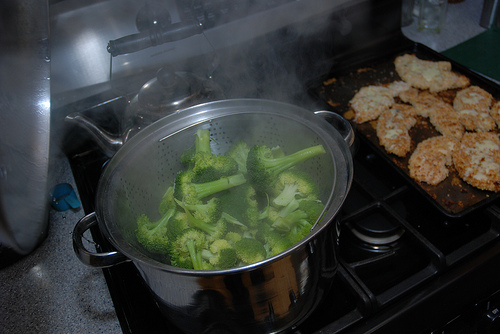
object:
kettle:
[63, 19, 227, 159]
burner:
[347, 205, 405, 254]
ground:
[320, 45, 352, 60]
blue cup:
[48, 182, 81, 212]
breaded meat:
[348, 53, 500, 191]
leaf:
[246, 144, 279, 196]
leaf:
[135, 214, 170, 256]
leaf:
[180, 149, 237, 182]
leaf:
[234, 237, 268, 264]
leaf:
[299, 199, 327, 220]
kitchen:
[0, 0, 498, 334]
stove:
[61, 34, 500, 334]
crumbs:
[431, 192, 474, 213]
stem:
[274, 144, 326, 173]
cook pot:
[72, 98, 356, 334]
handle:
[312, 110, 354, 147]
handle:
[72, 210, 132, 269]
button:
[135, 4, 171, 32]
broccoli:
[133, 128, 326, 270]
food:
[396, 52, 469, 92]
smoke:
[95, 0, 322, 117]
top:
[0, 0, 500, 334]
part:
[348, 267, 423, 310]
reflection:
[131, 246, 310, 323]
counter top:
[0, 147, 123, 334]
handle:
[106, 19, 204, 57]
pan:
[304, 42, 500, 218]